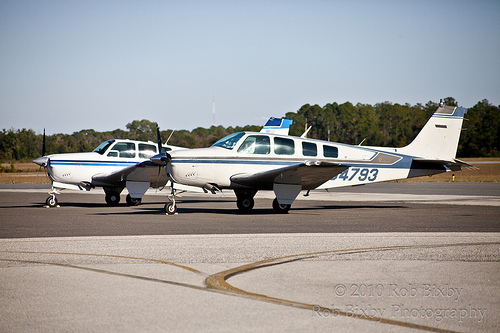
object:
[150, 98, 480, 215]
plane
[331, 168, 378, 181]
number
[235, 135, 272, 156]
window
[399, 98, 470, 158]
tail wing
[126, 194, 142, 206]
tire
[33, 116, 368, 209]
airplane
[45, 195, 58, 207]
front tire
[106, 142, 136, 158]
window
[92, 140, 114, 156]
windshield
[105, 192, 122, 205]
tire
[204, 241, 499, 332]
pattern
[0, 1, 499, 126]
sky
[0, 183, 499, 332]
ground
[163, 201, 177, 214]
wheel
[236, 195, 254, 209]
back wheel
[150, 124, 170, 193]
propeller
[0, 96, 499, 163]
trees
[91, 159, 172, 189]
wing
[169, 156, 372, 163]
stripe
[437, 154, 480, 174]
tail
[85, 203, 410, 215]
shadows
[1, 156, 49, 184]
grass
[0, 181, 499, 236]
landing lane